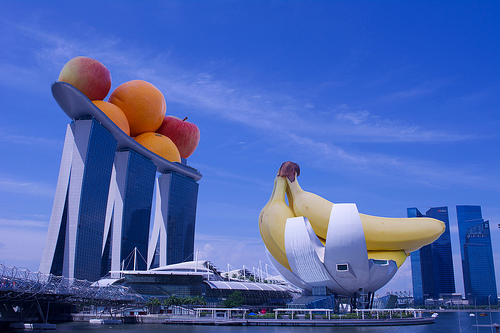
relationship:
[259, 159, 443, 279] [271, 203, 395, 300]
banana bunch on top of building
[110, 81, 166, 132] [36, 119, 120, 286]
orange on top of building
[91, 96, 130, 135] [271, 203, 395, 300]
orange on top of building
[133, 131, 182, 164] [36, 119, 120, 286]
orange on top of building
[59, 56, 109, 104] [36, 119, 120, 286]
apple on top of building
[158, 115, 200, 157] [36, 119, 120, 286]
apple on top of building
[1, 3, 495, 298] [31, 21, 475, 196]
sky has cloud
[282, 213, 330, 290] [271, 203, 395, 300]
roof top on building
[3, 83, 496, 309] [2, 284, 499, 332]
city near water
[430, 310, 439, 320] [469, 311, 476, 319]
boat next to boat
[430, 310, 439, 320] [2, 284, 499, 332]
boat on top of water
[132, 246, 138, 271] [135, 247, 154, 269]
pole coming down pole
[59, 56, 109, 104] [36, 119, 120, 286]
apple on building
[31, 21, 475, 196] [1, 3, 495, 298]
cloud in sky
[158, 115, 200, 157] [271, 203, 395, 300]
apple on top of building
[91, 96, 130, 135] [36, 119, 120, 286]
orange on top of building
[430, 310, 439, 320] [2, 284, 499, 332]
boat in water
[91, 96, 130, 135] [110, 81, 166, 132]
orange piled on orange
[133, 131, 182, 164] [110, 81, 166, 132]
orange piled on orange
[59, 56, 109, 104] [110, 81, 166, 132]
apple in pile with orange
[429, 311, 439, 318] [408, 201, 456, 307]
boat next to building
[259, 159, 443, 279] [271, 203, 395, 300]
banana bunch in building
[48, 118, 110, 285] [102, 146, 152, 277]
building next to building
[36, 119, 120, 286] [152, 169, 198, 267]
building next to building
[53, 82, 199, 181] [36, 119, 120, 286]
board on top of building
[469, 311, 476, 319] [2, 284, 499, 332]
boat on top of water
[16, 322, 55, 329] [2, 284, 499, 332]
dock on top of water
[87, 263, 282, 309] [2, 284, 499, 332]
cruise ship next to water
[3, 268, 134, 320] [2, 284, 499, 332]
bridge over water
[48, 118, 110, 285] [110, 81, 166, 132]
building under orange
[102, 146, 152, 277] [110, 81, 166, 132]
building under orange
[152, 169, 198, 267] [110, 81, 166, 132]
building under orange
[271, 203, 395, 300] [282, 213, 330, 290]
building has roof top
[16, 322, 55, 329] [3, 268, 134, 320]
dock under bridge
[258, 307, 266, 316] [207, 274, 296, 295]
structure under arch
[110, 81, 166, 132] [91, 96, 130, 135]
orange next to orange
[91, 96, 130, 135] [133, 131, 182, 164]
orange next to orange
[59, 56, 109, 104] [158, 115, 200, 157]
apple on top with apple